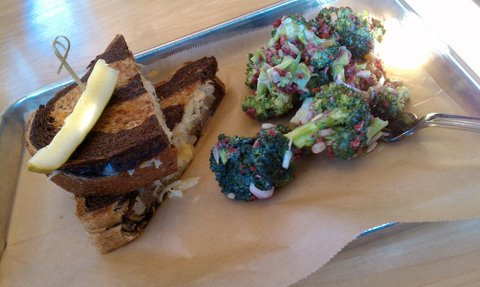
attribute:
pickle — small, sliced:
[52, 71, 119, 196]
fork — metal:
[358, 95, 479, 139]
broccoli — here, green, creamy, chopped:
[251, 54, 352, 173]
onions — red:
[269, 116, 316, 172]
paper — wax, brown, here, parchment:
[170, 212, 321, 259]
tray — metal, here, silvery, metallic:
[168, 19, 301, 44]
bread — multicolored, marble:
[118, 81, 182, 171]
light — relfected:
[378, 6, 433, 87]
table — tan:
[87, 6, 203, 32]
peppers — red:
[271, 43, 296, 68]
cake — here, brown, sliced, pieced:
[101, 119, 127, 158]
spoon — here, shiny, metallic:
[371, 112, 444, 145]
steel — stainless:
[422, 106, 462, 134]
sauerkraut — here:
[162, 112, 202, 145]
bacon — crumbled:
[257, 46, 297, 60]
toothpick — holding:
[41, 39, 133, 116]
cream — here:
[380, 18, 462, 101]